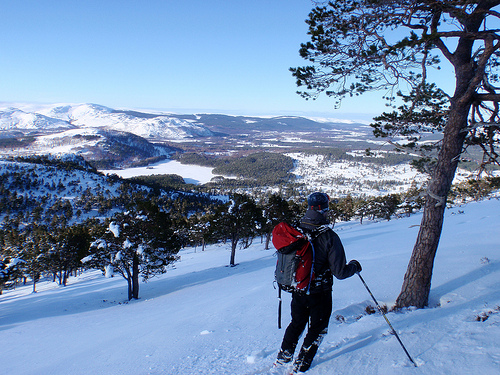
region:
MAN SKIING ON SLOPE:
[222, 182, 399, 330]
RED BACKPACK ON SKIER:
[267, 204, 314, 309]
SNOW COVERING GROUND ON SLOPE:
[98, 241, 423, 362]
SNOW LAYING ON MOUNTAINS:
[124, 129, 200, 209]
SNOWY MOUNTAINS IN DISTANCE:
[7, 87, 401, 152]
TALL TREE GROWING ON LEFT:
[342, 14, 481, 244]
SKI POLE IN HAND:
[348, 234, 493, 355]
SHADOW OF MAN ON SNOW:
[297, 288, 373, 370]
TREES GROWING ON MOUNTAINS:
[248, 166, 276, 183]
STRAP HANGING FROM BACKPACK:
[268, 275, 289, 330]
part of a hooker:
[367, 286, 423, 331]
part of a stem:
[397, 248, 429, 318]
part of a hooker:
[352, 258, 417, 307]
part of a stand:
[224, 298, 261, 335]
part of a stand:
[368, 294, 408, 322]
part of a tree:
[391, 260, 407, 317]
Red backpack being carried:
[269, 223, 317, 301]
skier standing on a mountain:
[271, 184, 421, 373]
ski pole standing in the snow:
[357, 270, 422, 373]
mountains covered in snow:
[2, 87, 498, 215]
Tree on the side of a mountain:
[284, 16, 498, 309]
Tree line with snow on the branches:
[9, 193, 393, 310]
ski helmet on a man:
[305, 189, 332, 222]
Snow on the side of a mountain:
[0, 194, 498, 372]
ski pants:
[274, 284, 335, 373]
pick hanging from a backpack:
[269, 279, 286, 334]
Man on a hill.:
[251, 183, 417, 366]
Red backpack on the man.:
[267, 221, 317, 288]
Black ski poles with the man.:
[265, 255, 425, 362]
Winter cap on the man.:
[297, 190, 336, 221]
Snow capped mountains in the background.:
[0, 93, 492, 165]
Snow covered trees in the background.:
[1, 147, 498, 299]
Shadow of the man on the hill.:
[303, 281, 498, 368]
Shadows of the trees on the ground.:
[1, 213, 498, 330]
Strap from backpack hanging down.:
[270, 284, 292, 331]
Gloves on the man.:
[342, 260, 362, 275]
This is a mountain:
[56, 92, 198, 158]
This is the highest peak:
[20, 73, 181, 186]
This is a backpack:
[247, 233, 374, 361]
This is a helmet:
[246, 163, 413, 273]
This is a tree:
[393, 52, 493, 232]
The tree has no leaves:
[352, 2, 480, 129]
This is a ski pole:
[314, 285, 394, 318]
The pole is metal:
[321, 235, 483, 364]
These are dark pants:
[259, 292, 364, 372]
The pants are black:
[220, 285, 286, 353]